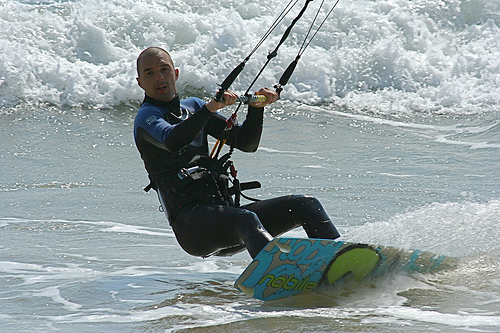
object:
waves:
[2, 3, 498, 132]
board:
[232, 238, 476, 299]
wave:
[1, 25, 134, 121]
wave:
[219, 4, 499, 99]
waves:
[0, 9, 499, 115]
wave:
[9, 1, 498, 137]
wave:
[363, 190, 438, 240]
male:
[133, 44, 339, 256]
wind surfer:
[206, 0, 449, 287]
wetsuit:
[133, 98, 343, 255]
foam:
[319, 19, 466, 110]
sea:
[0, 0, 499, 331]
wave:
[60, 265, 229, 297]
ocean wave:
[2, 212, 177, 240]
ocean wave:
[2, 252, 229, 279]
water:
[4, 97, 499, 329]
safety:
[143, 146, 253, 209]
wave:
[295, 29, 412, 126]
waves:
[5, 2, 498, 119]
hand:
[251, 88, 277, 105]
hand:
[208, 90, 244, 112]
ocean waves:
[302, 27, 475, 173]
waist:
[142, 155, 252, 211]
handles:
[252, 91, 268, 101]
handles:
[235, 92, 243, 102]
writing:
[268, 275, 285, 289]